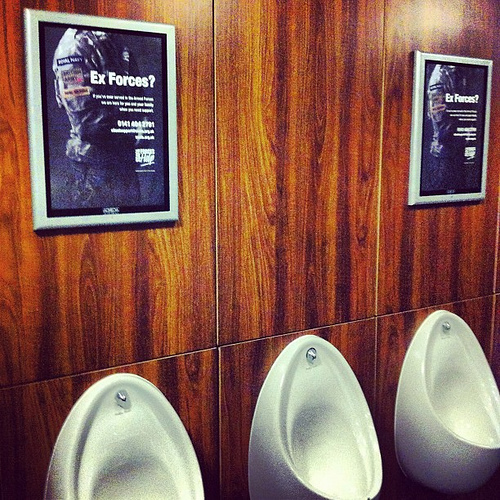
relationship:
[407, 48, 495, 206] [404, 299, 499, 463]
ad above urinal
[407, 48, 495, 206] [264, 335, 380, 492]
ad above urinal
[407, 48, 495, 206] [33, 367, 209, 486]
ad above urinal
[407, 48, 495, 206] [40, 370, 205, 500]
ad above urinals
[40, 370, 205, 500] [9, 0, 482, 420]
urinals on wall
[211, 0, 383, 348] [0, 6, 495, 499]
wood panels on wall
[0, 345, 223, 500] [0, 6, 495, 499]
wood panels on wall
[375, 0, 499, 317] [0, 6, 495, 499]
wood panels on wall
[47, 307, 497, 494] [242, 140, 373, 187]
urinals on wall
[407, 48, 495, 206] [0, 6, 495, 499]
ad on wall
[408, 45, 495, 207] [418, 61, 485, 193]
silver frame on picture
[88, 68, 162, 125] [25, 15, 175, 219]
words on picture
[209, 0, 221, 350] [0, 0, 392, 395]
line between two panels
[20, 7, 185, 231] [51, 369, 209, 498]
advertisement above urinal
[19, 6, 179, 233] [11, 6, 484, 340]
ad on wall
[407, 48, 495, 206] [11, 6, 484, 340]
ad on wall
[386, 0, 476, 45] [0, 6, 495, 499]
light reflection on wall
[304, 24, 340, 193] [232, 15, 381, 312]
wood grain on panel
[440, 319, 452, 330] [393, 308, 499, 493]
shiny metal on urinal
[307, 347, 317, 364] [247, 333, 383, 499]
shiny metal on urinal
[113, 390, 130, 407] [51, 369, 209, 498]
shiny metal on urinal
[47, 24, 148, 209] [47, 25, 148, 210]
man has body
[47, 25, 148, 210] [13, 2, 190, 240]
body on picture